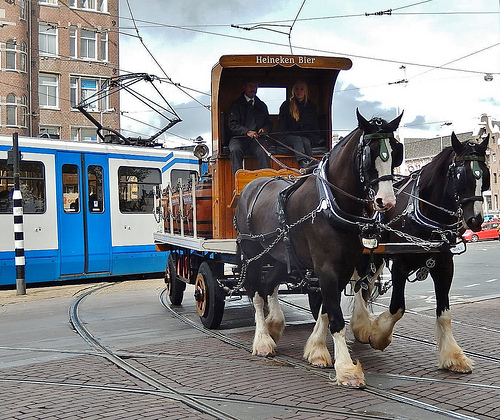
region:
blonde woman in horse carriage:
[282, 80, 322, 166]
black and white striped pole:
[11, 133, 30, 294]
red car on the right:
[463, 218, 498, 240]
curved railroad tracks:
[68, 278, 478, 419]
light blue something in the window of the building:
[81, 78, 96, 88]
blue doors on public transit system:
[56, 150, 109, 272]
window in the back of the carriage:
[256, 86, 286, 113]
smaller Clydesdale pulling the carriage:
[347, 128, 492, 373]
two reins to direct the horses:
[253, 131, 318, 173]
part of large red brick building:
[1, 5, 119, 140]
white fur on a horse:
[238, 278, 377, 406]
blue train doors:
[58, 146, 120, 278]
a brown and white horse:
[225, 108, 411, 386]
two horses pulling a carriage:
[242, 116, 494, 381]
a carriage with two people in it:
[142, 43, 385, 323]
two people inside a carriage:
[232, 78, 332, 182]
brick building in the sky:
[2, 1, 137, 146]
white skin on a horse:
[373, 146, 400, 216]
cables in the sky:
[59, 0, 497, 147]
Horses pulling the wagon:
[222, 107, 496, 382]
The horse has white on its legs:
[236, 263, 379, 389]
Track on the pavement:
[50, 286, 180, 403]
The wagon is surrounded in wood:
[136, 163, 238, 265]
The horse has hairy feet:
[322, 323, 369, 412]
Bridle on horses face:
[345, 140, 415, 212]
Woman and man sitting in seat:
[227, 72, 331, 162]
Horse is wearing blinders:
[352, 135, 371, 166]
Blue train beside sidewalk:
[4, 125, 189, 254]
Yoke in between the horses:
[350, 225, 472, 282]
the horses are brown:
[243, 120, 462, 290]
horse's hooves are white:
[229, 298, 478, 387]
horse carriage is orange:
[136, 31, 353, 275]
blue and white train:
[0, 101, 192, 273]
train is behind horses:
[0, 104, 173, 297]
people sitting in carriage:
[234, 66, 315, 166]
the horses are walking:
[248, 94, 467, 379]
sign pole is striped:
[3, 182, 45, 289]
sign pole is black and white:
[7, 186, 42, 305]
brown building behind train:
[0, 1, 134, 141]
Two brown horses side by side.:
[220, 107, 496, 382]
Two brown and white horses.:
[240, 105, 490, 382]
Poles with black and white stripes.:
[5, 126, 25, 296]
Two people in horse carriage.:
[226, 75, 321, 165]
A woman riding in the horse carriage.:
[275, 75, 321, 161]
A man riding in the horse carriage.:
[225, 76, 272, 161]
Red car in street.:
[461, 217, 496, 242]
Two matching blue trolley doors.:
[52, 145, 109, 277]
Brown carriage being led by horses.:
[155, 45, 480, 385]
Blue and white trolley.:
[0, 133, 206, 286]